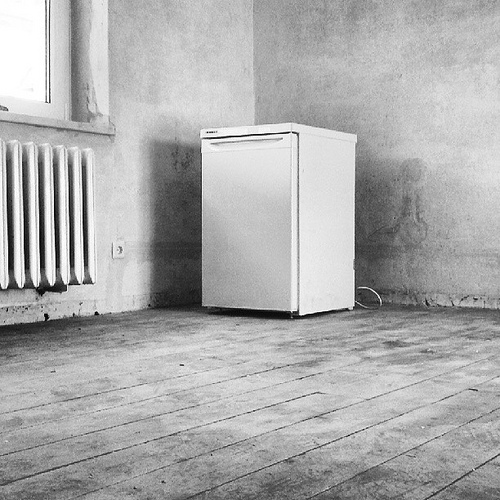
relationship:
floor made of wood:
[1, 311, 494, 495] [79, 358, 493, 498]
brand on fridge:
[204, 130, 219, 135] [196, 122, 360, 319]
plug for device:
[113, 238, 129, 258] [196, 122, 360, 319]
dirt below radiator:
[1, 314, 119, 354] [0, 140, 103, 291]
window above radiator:
[2, 6, 51, 108] [0, 140, 103, 291]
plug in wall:
[113, 238, 129, 258] [2, 0, 259, 327]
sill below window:
[2, 100, 114, 137] [2, 6, 51, 108]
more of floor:
[2, 301, 498, 500] [1, 311, 494, 495]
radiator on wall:
[0, 140, 103, 291] [2, 0, 259, 327]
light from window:
[2, 2, 48, 108] [2, 6, 51, 108]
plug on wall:
[113, 238, 129, 258] [2, 0, 259, 327]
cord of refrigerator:
[355, 284, 384, 310] [196, 122, 360, 319]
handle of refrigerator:
[206, 133, 297, 149] [196, 122, 360, 319]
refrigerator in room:
[196, 122, 360, 319] [2, 2, 500, 499]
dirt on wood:
[1, 314, 119, 354] [1, 311, 494, 495]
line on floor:
[2, 354, 500, 398] [1, 311, 494, 495]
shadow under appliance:
[157, 302, 359, 325] [196, 122, 360, 319]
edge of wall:
[246, 1, 261, 120] [255, 3, 498, 310]